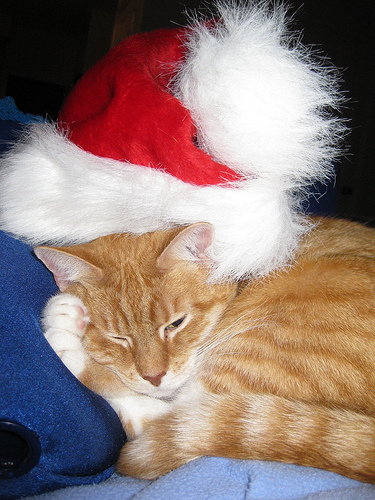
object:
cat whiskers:
[180, 312, 269, 364]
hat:
[0, 0, 351, 292]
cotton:
[161, 2, 356, 189]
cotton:
[1, 116, 324, 287]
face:
[61, 233, 222, 400]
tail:
[112, 385, 375, 490]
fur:
[307, 275, 352, 310]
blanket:
[182, 468, 282, 498]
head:
[33, 220, 242, 400]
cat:
[32, 210, 375, 486]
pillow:
[0, 85, 134, 500]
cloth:
[1, 15, 344, 272]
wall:
[0, 0, 218, 122]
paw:
[42, 327, 88, 370]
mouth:
[113, 354, 198, 404]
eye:
[154, 311, 192, 335]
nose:
[136, 357, 170, 386]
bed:
[0, 98, 375, 500]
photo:
[2, 2, 375, 499]